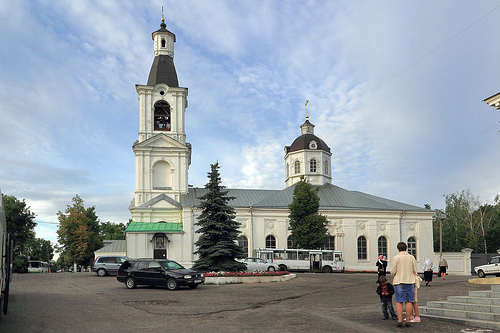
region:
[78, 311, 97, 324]
Small part of black street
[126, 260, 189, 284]
Black car on the street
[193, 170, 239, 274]
Christmas tree in the center of the driveway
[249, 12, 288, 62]
Clouds in the sky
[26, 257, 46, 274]
Green and white bus in the background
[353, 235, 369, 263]
Black window of the church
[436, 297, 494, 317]
A couple of gray steps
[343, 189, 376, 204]
Gray roof of church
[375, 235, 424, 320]
Little boy with his mom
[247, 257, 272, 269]
Gray car in driveway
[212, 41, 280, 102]
clouds in the sky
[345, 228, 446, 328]
people on the ground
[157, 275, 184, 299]
tire on the car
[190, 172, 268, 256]
tree next to building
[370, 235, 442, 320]
adult and some kids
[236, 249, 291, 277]
white car in background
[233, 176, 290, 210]
roof of the building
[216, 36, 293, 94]
blue sky behind the clouds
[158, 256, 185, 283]
window on the car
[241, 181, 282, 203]
silver roof of the building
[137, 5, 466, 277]
large white church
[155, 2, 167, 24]
steeple on top of church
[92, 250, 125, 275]
blue van parked beside the church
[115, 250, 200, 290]
black station wagon in the church parking lot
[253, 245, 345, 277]
white transit bus parked on the side of the church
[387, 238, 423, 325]
woman in white top and blue jean skirt walking toward the church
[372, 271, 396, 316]
little boy walking with woman in blue jean skirt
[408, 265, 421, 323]
part of a little girl walking with woman in the blue jean skirt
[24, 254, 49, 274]
transit bus appearing to be leaving the church parking lot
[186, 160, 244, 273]
large evergreen tree in a flower bed garden in the parking lot of the church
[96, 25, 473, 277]
a large white church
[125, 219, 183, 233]
small green awning on church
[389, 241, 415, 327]
man wearing blue shorts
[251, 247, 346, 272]
a white bus parked by church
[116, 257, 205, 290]
the car is black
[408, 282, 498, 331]
there are four steps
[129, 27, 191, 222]
a bell tower on the church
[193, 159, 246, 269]
tall, green pine tree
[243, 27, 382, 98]
white clouds in a blue sky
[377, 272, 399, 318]
small child in a black jacket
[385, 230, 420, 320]
the man wears shorts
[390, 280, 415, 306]
the shorts are blue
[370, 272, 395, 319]
the boy is standing infront of the man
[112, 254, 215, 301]
the car is parked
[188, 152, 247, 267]
the tree is pointy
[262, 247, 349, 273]
the bus is white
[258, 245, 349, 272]
the bus has a door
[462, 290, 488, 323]
the steps are gray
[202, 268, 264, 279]
the flowers are red